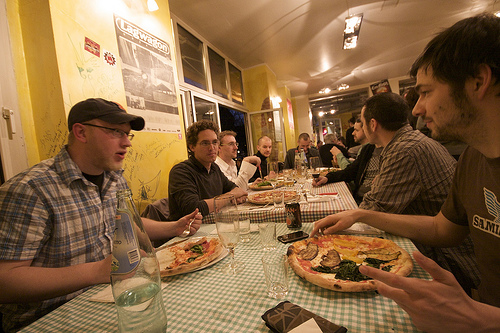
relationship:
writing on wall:
[31, 113, 170, 219] [0, 1, 190, 219]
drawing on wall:
[134, 165, 165, 213] [0, 1, 190, 219]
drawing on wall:
[66, 42, 112, 98] [0, 1, 190, 219]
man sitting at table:
[2, 77, 209, 313] [199, 199, 377, 322]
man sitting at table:
[163, 116, 250, 214] [199, 199, 377, 322]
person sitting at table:
[401, 13, 491, 277] [199, 199, 377, 322]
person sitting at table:
[347, 86, 438, 206] [199, 199, 377, 322]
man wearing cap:
[2, 77, 209, 313] [55, 89, 151, 134]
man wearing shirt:
[2, 77, 209, 313] [5, 140, 149, 310]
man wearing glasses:
[2, 77, 209, 313] [224, 140, 242, 147]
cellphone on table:
[276, 228, 308, 245] [16, 216, 419, 329]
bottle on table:
[103, 181, 171, 331] [9, 150, 429, 330]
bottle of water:
[103, 181, 171, 331] [115, 278, 167, 328]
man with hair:
[163, 116, 250, 214] [183, 121, 219, 146]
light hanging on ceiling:
[336, 12, 364, 60] [168, 3, 494, 92]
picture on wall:
[103, 46, 119, 68] [4, 6, 193, 240]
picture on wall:
[78, 30, 102, 58] [4, 6, 193, 240]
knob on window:
[1, 107, 18, 142] [3, 97, 9, 191]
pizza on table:
[284, 225, 419, 297] [16, 216, 419, 329]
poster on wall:
[113, 12, 182, 136] [46, 0, 190, 210]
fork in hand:
[174, 210, 199, 242] [172, 205, 205, 240]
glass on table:
[263, 251, 293, 300] [164, 273, 259, 331]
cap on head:
[55, 89, 151, 134] [62, 101, 135, 174]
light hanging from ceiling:
[336, 12, 364, 60] [167, 2, 498, 110]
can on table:
[282, 200, 304, 232] [16, 216, 419, 329]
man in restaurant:
[2, 77, 209, 313] [4, 2, 494, 325]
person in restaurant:
[356, 90, 455, 225] [4, 2, 494, 325]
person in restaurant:
[212, 125, 262, 186] [4, 2, 494, 325]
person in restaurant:
[281, 130, 326, 167] [4, 2, 494, 325]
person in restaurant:
[329, 112, 370, 169] [4, 2, 494, 325]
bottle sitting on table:
[103, 181, 171, 331] [15, 218, 450, 331]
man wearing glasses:
[2, 77, 209, 313] [75, 120, 133, 137]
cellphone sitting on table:
[276, 228, 308, 245] [53, 213, 438, 330]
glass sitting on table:
[263, 251, 286, 299] [48, 215, 421, 322]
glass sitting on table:
[257, 220, 277, 252] [48, 215, 421, 322]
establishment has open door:
[50, 65, 443, 319] [218, 107, 250, 175]